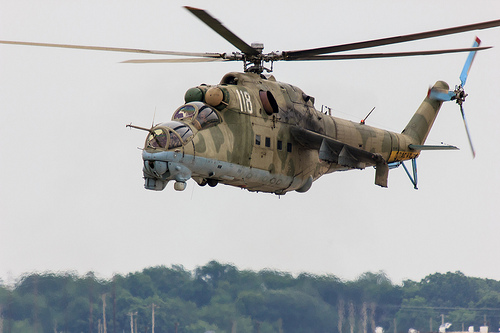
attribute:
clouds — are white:
[281, 199, 445, 254]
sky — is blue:
[44, 107, 218, 269]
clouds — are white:
[88, 204, 194, 267]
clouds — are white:
[23, 159, 140, 274]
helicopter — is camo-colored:
[136, 81, 361, 204]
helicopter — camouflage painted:
[2, 3, 492, 197]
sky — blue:
[42, 84, 124, 181]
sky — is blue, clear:
[1, 4, 496, 286]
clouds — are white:
[0, 3, 500, 292]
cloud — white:
[351, 194, 498, 274]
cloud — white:
[14, 5, 496, 278]